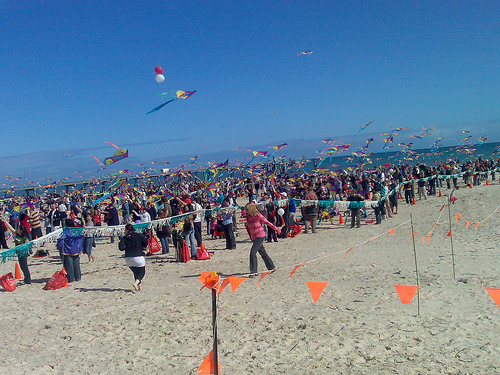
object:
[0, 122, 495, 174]
kites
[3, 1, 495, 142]
sky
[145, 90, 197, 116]
kite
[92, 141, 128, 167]
kite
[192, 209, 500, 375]
flag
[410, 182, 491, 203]
cone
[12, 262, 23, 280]
cone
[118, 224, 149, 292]
woman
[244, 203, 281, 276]
woman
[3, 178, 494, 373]
beach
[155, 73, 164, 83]
balloon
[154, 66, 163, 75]
balloon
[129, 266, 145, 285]
pants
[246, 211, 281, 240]
shirt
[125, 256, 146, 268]
under-shirt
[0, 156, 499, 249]
people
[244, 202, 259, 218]
hair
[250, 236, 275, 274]
pants